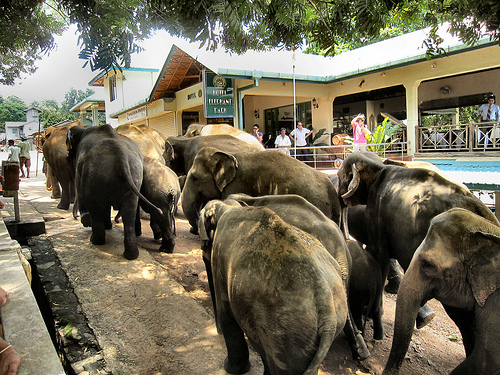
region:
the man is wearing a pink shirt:
[351, 121, 368, 142]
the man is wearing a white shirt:
[290, 128, 308, 147]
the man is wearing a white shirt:
[272, 133, 292, 145]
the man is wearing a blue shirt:
[251, 131, 263, 143]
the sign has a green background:
[205, 83, 237, 117]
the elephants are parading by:
[42, 119, 495, 374]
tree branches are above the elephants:
[1, 1, 496, 91]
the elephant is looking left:
[182, 140, 337, 249]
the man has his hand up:
[351, 112, 367, 147]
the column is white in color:
[400, 80, 423, 154]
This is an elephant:
[67, 124, 141, 266]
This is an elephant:
[132, 147, 186, 267]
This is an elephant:
[27, 125, 82, 199]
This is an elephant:
[191, 192, 349, 373]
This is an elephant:
[227, 182, 365, 296]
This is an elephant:
[372, 200, 492, 374]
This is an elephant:
[324, 131, 496, 275]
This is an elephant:
[171, 140, 363, 230]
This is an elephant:
[155, 130, 276, 174]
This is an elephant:
[177, 112, 272, 147]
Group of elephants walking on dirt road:
[45, 143, 423, 345]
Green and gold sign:
[194, 70, 238, 125]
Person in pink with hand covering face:
[345, 115, 370, 149]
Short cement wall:
[1, 240, 58, 374]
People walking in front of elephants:
[2, 129, 36, 178]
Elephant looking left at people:
[401, 210, 498, 328]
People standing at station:
[250, 74, 391, 154]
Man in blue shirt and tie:
[464, 92, 499, 146]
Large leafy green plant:
[358, 123, 405, 158]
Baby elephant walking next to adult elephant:
[130, 153, 185, 253]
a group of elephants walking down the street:
[32, 111, 499, 373]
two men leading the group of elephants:
[2, 125, 34, 187]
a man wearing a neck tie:
[472, 93, 498, 145]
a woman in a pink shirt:
[345, 109, 373, 158]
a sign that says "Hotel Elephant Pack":
[198, 83, 240, 124]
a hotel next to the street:
[44, 41, 498, 221]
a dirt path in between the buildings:
[12, 133, 494, 373]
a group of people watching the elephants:
[241, 83, 498, 171]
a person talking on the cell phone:
[244, 121, 265, 151]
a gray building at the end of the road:
[0, 106, 61, 156]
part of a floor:
[130, 292, 175, 333]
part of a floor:
[150, 296, 204, 361]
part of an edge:
[33, 272, 75, 334]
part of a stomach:
[236, 250, 273, 316]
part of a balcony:
[419, 51, 467, 123]